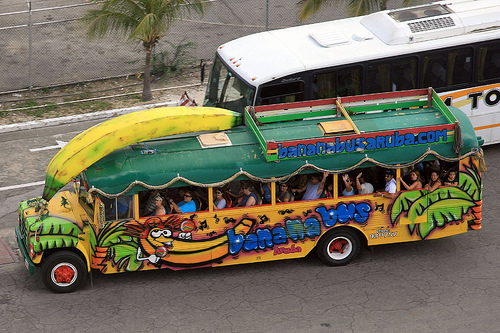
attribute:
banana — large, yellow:
[41, 105, 243, 203]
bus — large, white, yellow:
[14, 85, 487, 293]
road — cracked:
[1, 116, 500, 332]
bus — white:
[201, 0, 500, 147]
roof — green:
[86, 101, 474, 186]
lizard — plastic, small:
[60, 195, 75, 212]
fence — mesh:
[0, 0, 438, 95]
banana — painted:
[132, 216, 258, 265]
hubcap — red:
[53, 262, 76, 283]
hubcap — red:
[328, 237, 349, 255]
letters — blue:
[226, 199, 373, 255]